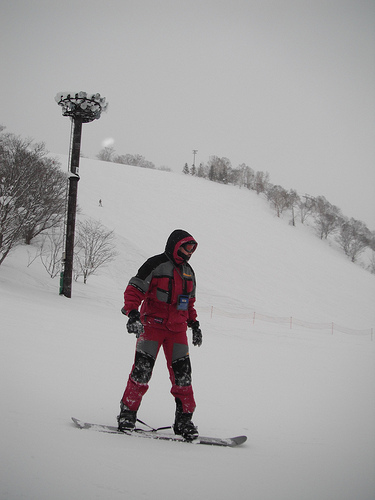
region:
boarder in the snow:
[91, 209, 251, 459]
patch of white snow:
[275, 459, 300, 482]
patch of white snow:
[145, 460, 178, 495]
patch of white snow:
[283, 397, 309, 426]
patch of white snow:
[35, 426, 82, 466]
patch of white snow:
[43, 379, 81, 410]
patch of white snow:
[19, 426, 43, 459]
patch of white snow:
[36, 356, 74, 389]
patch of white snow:
[289, 385, 339, 419]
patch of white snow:
[295, 450, 328, 483]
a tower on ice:
[49, 85, 115, 126]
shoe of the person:
[165, 400, 219, 460]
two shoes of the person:
[99, 397, 225, 450]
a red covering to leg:
[114, 371, 212, 416]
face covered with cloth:
[166, 221, 202, 260]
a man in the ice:
[94, 213, 253, 493]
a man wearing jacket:
[134, 226, 216, 346]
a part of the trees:
[8, 160, 87, 290]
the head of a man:
[163, 223, 226, 271]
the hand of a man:
[122, 304, 165, 336]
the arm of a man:
[121, 249, 178, 348]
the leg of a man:
[111, 344, 175, 427]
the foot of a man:
[97, 411, 157, 447]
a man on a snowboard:
[85, 221, 278, 440]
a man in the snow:
[60, 241, 278, 446]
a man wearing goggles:
[170, 223, 208, 263]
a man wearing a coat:
[109, 242, 234, 343]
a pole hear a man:
[34, 184, 332, 313]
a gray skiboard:
[73, 410, 247, 449]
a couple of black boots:
[116, 407, 196, 437]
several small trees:
[205, 158, 371, 259]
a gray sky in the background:
[7, 10, 372, 58]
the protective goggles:
[182, 240, 197, 252]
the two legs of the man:
[121, 338, 198, 438]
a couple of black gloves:
[123, 309, 204, 345]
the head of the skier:
[164, 228, 198, 261]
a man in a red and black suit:
[108, 229, 202, 439]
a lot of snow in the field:
[261, 247, 364, 477]